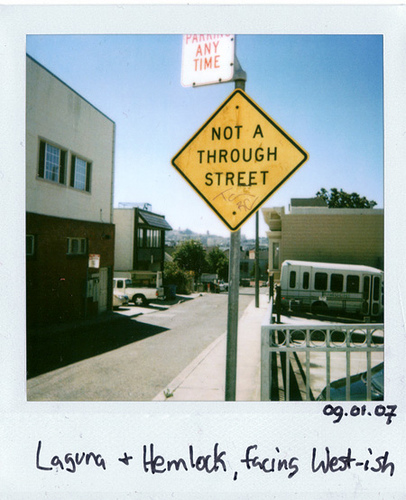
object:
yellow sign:
[167, 79, 312, 234]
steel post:
[217, 228, 249, 408]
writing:
[32, 430, 398, 485]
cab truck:
[110, 268, 168, 310]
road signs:
[165, 87, 314, 233]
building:
[14, 47, 122, 364]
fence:
[254, 318, 393, 407]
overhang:
[138, 208, 174, 233]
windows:
[42, 138, 62, 184]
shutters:
[35, 132, 46, 185]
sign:
[176, 33, 237, 88]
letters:
[192, 57, 200, 71]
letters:
[203, 55, 213, 71]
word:
[192, 37, 221, 60]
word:
[192, 53, 221, 73]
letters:
[213, 54, 222, 69]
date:
[319, 397, 399, 430]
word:
[28, 436, 119, 481]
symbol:
[114, 448, 136, 470]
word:
[138, 439, 230, 479]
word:
[241, 440, 301, 485]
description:
[29, 393, 399, 500]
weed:
[160, 385, 176, 401]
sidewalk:
[155, 289, 282, 407]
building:
[111, 199, 175, 277]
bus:
[275, 256, 384, 327]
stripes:
[281, 289, 311, 299]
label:
[31, 434, 397, 487]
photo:
[26, 33, 385, 401]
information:
[189, 117, 282, 189]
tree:
[312, 184, 380, 212]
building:
[260, 198, 388, 324]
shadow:
[21, 294, 172, 385]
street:
[25, 273, 261, 398]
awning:
[138, 210, 175, 234]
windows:
[134, 226, 146, 248]